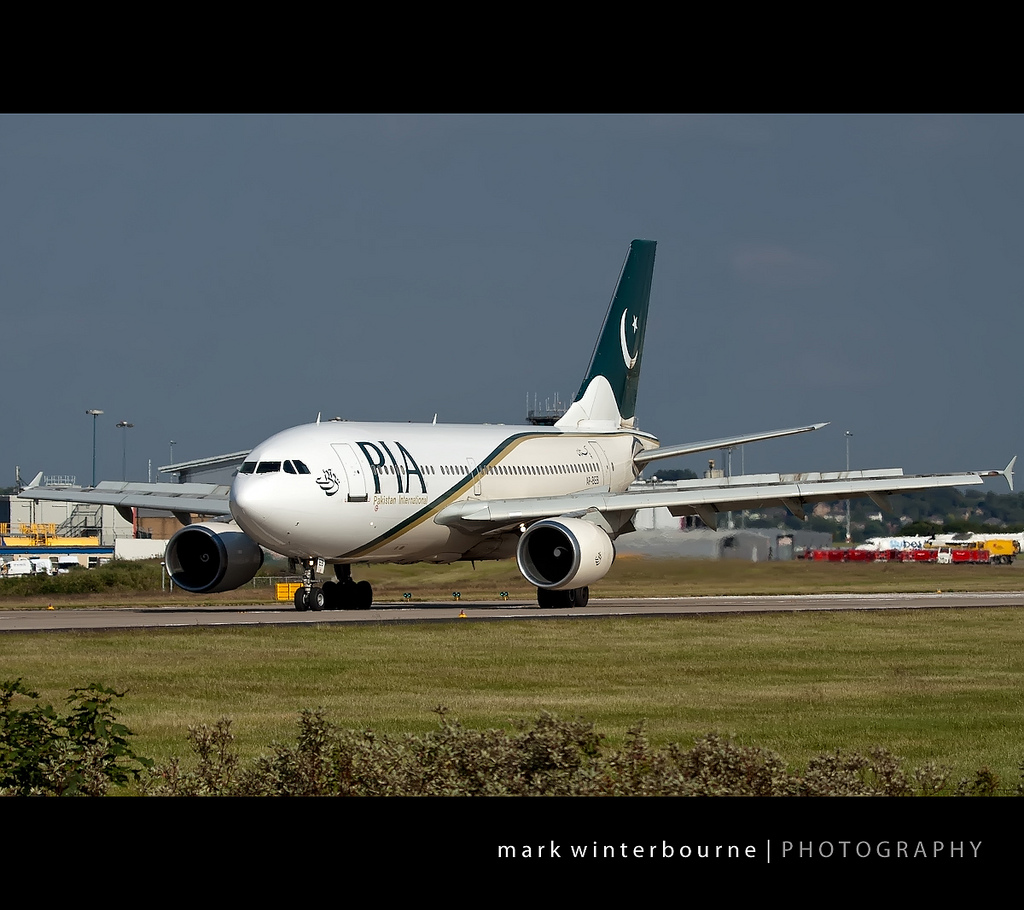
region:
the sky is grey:
[73, 130, 544, 349]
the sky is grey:
[51, 7, 998, 808]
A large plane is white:
[158, 226, 852, 655]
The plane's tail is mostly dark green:
[565, 183, 734, 444]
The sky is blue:
[44, 135, 504, 382]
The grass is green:
[253, 636, 420, 717]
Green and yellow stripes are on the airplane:
[337, 367, 660, 604]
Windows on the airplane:
[218, 433, 321, 505]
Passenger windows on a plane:
[353, 443, 626, 497]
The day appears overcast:
[23, 125, 1011, 749]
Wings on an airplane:
[499, 369, 992, 601]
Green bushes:
[19, 661, 822, 803]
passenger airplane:
[190, 224, 870, 624]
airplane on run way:
[157, 230, 932, 620]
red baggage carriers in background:
[795, 519, 1021, 597]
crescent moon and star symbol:
[535, 205, 688, 477]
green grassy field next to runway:
[108, 632, 968, 716]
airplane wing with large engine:
[460, 472, 1020, 596]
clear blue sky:
[48, 173, 543, 379]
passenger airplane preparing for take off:
[155, 301, 956, 615]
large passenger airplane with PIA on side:
[163, 377, 730, 613]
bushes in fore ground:
[58, 683, 1008, 792]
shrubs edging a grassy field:
[57, 621, 982, 795]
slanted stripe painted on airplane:
[314, 416, 599, 566]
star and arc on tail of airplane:
[571, 221, 698, 422]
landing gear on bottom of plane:
[275, 542, 406, 626]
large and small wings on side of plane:
[444, 407, 1008, 524]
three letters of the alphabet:
[359, 419, 433, 519]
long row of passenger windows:
[362, 442, 607, 484]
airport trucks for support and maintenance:
[810, 512, 1017, 573]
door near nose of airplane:
[228, 431, 381, 556]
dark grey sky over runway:
[99, 179, 902, 437]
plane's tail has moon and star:
[530, 223, 731, 446]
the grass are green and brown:
[76, 643, 863, 738]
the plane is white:
[227, 433, 756, 582]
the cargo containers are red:
[805, 542, 1018, 594]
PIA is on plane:
[345, 434, 462, 536]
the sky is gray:
[47, 171, 482, 353]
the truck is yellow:
[973, 533, 1021, 562]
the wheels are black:
[279, 577, 363, 613]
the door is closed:
[463, 448, 499, 502]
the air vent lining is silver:
[511, 514, 607, 595]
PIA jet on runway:
[19, 182, 981, 617]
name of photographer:
[483, 806, 1009, 886]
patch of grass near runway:
[164, 631, 1002, 709]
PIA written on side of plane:
[349, 423, 430, 501]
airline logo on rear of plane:
[613, 299, 648, 376]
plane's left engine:
[503, 512, 620, 595]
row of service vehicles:
[804, 517, 1021, 576]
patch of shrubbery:
[3, 679, 158, 804]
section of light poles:
[73, 378, 191, 487]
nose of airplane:
[234, 460, 326, 530]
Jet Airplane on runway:
[223, 238, 888, 594]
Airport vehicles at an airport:
[779, 506, 1017, 589]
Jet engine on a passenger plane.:
[504, 512, 625, 598]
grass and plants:
[17, 630, 1013, 792]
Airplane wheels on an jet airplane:
[282, 550, 388, 624]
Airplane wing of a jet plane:
[463, 459, 992, 504]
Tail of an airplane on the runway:
[523, 228, 666, 426]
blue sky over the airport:
[7, 115, 513, 398]